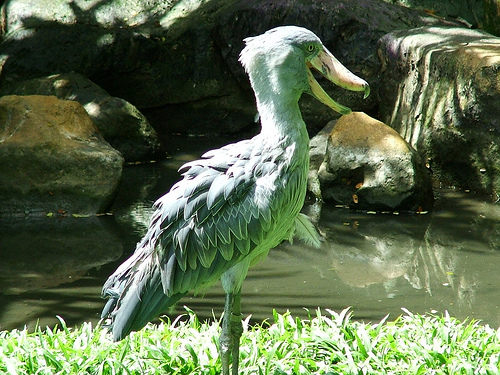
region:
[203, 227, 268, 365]
legs on the bird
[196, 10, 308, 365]
animal is in grass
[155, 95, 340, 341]
the feathers on bird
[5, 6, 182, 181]
the rocks are brown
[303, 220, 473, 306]
reflection on the water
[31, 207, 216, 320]
the water is gray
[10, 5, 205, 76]
sunlight is on rocks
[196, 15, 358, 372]
the animal is a figure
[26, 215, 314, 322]
the water is dirty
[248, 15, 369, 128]
the beak is on animal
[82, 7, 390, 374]
gray bird standing on the grass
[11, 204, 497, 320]
pond next to the bird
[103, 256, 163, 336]
tail feathers of the gray bird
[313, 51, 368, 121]
open beak of the bird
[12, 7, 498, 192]
large stones lining the pond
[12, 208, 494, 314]
shadows on the pond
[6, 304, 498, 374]
grass the gray bird is standing on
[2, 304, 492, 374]
sunlight on the grass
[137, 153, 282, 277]
gray feathers on the bird's body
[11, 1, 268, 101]
shadows on the stone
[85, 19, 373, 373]
Bird with gray feathers by water.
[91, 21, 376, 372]
Gray bird with a hooked beak.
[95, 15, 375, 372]
Yellow eye of a gray bird.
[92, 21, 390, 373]
Bird with hooked beak standing in green grass.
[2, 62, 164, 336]
Stones next to dirty water.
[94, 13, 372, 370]
Gray legs of bird next to water.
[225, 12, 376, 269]
Feather out of place on birds chest.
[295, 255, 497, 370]
Sunlight shining on green grass.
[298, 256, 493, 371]
Grass growing on the edge of dirty water..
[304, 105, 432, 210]
Small boulder with holes in it.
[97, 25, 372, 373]
large bird standing on top of grass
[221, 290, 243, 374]
the bird has long gray legs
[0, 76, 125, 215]
large rock next to the water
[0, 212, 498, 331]
the water is brown and murky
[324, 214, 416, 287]
reflection of a rock in the water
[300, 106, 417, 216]
rock behind bird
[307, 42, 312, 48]
the bird has a small beady eye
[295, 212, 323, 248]
small downy feather near abdomen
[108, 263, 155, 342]
gray tail feather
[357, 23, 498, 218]
large boulder behind rock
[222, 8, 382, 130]
the bird has a big beak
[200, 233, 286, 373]
the birds legs are skinny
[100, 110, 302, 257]
the bird has tons of feathers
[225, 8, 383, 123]
the bird has its mouth open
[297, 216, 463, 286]
the reflection of the rock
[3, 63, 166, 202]
there is large brown rocks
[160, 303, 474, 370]
the bird is standing in grass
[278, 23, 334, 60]
the birds eye is open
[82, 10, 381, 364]
the bird is standing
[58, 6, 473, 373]
the bird is near a pond